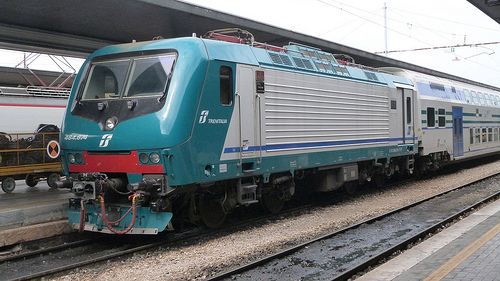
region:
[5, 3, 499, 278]
Exterior shot, overcast day.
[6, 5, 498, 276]
Outdoor view of public transportation site.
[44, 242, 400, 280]
Two railroad tracks.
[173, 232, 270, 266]
Gravel, between tracks.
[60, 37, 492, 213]
Blue, silver and red passenger train.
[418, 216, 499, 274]
Platform edge, with faded yellow line.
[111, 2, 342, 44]
Flat, platform roof.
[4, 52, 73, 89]
Metal detailing, near roof structure.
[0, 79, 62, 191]
Second vehicle.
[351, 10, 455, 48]
Overcast sky.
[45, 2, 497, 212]
the train is blue and white.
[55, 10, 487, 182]
two train cars on the track.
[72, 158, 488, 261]
gravel between tracks.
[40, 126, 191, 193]
red bumper on train.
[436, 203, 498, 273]
yellow stripe on ground.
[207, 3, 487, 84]
the sky is white.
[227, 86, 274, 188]
the railing is silver.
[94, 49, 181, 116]
the windows are transparent.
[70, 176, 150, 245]
the wires are red.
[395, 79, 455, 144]
the windows are black.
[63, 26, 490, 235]
teal blue bullet train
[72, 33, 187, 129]
windshield of a bullet train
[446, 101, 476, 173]
blue double door on a train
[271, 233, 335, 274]
railroad tracks with water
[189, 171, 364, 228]
train wheels on tracks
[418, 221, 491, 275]
yellow line on the edge of the platform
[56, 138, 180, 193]
red panel on the front of a train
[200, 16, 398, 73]
handles on top of a train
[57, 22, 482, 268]
train on an empty platform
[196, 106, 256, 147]
white lettering on a teal background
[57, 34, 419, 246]
Blue green train engine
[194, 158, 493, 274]
Tracks on right are empty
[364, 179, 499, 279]
Train station platform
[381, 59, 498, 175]
Passenger car behind engine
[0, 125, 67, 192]
Yellow cart on train platform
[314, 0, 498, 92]
Wires above a train station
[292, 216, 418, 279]
Water on the ground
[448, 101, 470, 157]
Blue doors on train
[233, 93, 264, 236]
Steps up into train engine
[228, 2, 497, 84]
Sky is white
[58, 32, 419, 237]
a green and silver train engine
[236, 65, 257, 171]
the side door entrance to the train engine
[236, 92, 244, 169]
the trains side door hand rails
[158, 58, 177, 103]
the windshield wiper on the front windshield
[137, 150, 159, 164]
the trains front headlights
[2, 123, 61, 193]
the train station luggage cart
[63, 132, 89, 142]
the trains identification number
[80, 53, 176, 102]
the train engines front windshield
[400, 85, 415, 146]
the rear side door of the train engine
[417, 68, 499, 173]
a train passenger car